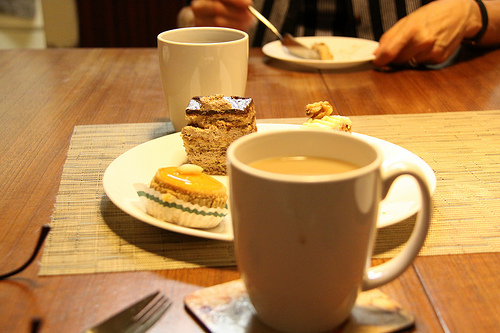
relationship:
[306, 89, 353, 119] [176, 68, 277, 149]
nut on cake